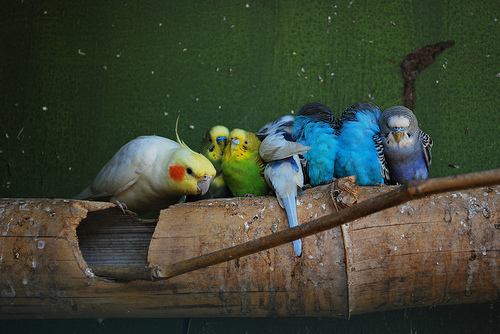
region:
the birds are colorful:
[95, 92, 448, 205]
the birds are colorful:
[111, 80, 481, 206]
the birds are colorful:
[79, 85, 441, 236]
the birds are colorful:
[71, 98, 435, 237]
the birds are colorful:
[79, 73, 477, 267]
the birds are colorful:
[81, 82, 442, 229]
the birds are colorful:
[85, 79, 442, 251]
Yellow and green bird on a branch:
[191, 87, 268, 199]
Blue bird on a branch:
[253, 120, 320, 216]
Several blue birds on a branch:
[278, 98, 443, 178]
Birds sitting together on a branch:
[88, 90, 431, 199]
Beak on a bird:
[194, 173, 219, 196]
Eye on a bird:
[180, 160, 202, 179]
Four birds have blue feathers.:
[259, 100, 431, 183]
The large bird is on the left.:
[74, 132, 213, 198]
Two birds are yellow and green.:
[198, 119, 271, 197]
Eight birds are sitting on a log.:
[90, 97, 438, 196]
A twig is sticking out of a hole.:
[91, 252, 240, 283]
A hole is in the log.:
[62, 187, 186, 284]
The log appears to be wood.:
[7, 191, 497, 323]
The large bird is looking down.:
[88, 119, 220, 199]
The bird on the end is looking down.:
[377, 99, 432, 184]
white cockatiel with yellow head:
[75, 110, 217, 201]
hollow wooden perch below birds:
[0, 166, 497, 311]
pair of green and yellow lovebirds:
[195, 115, 261, 195]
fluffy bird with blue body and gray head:
[376, 95, 431, 185]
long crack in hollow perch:
[70, 165, 496, 287]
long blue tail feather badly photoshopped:
[272, 181, 307, 256]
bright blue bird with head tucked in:
[335, 100, 386, 190]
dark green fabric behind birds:
[0, 80, 496, 195]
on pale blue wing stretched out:
[255, 127, 315, 163]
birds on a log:
[77, 79, 442, 208]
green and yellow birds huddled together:
[200, 117, 262, 197]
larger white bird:
[90, 126, 207, 211]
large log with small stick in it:
[8, 189, 489, 315]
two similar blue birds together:
[304, 100, 388, 192]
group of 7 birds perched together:
[93, 90, 433, 186]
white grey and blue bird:
[375, 88, 439, 181]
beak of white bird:
[192, 176, 219, 201]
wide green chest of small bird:
[225, 151, 271, 196]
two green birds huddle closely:
[191, 126, 262, 201]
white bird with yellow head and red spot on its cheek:
[69, 127, 214, 207]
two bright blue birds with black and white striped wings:
[300, 103, 385, 190]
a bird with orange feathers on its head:
[164, 146, 219, 195]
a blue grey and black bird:
[380, 102, 433, 184]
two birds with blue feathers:
[298, 97, 384, 182]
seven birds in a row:
[83, 95, 463, 237]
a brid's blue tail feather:
[275, 187, 311, 264]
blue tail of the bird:
[282, 195, 305, 250]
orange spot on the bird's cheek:
[169, 165, 187, 180]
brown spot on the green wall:
[403, 34, 461, 99]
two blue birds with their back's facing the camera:
[294, 108, 384, 178]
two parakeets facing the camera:
[203, 123, 251, 166]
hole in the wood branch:
[76, 203, 165, 271]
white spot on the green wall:
[206, 63, 231, 82]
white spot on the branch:
[36, 234, 48, 250]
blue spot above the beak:
[219, 136, 224, 142]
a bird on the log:
[221, 126, 256, 195]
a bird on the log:
[201, 120, 243, 193]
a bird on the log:
[259, 105, 316, 247]